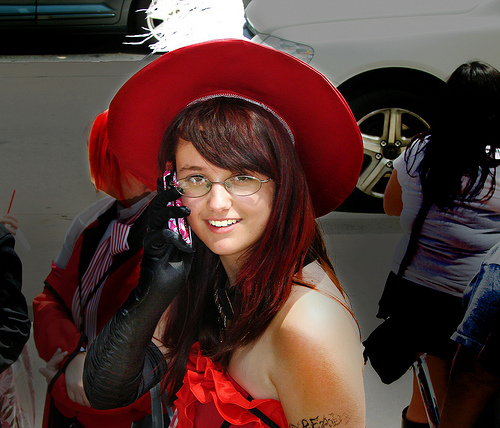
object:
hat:
[100, 30, 366, 234]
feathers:
[120, 32, 154, 48]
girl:
[77, 94, 372, 428]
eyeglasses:
[168, 170, 273, 198]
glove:
[80, 186, 196, 414]